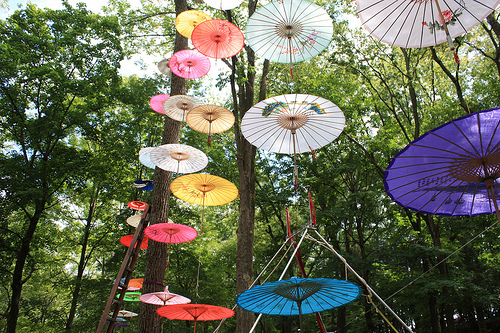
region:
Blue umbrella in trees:
[237, 272, 369, 316]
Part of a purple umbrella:
[375, 113, 497, 230]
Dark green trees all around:
[7, 20, 104, 295]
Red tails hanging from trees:
[272, 180, 338, 267]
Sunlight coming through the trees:
[114, 44, 156, 76]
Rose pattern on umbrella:
[422, 5, 477, 36]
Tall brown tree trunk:
[238, 163, 266, 273]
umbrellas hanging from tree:
[100, 6, 233, 328]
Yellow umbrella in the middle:
[172, 174, 244, 204]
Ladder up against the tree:
[113, 226, 136, 331]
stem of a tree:
[224, 233, 260, 286]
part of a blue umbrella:
[280, 282, 343, 308]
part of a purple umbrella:
[415, 142, 475, 209]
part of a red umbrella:
[166, 299, 230, 325]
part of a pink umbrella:
[153, 215, 188, 240]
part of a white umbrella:
[271, 115, 316, 162]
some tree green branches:
[11, 67, 88, 225]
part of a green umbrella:
[127, 292, 132, 307]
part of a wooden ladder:
[106, 278, 124, 298]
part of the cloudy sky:
[125, 47, 147, 72]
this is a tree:
[2, 10, 82, 331]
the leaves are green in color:
[11, 17, 88, 74]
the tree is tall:
[9, 8, 66, 327]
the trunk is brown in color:
[240, 158, 253, 288]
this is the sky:
[121, 57, 132, 75]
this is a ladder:
[107, 290, 121, 330]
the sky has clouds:
[120, 58, 136, 69]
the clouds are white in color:
[122, 56, 135, 79]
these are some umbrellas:
[159, 8, 206, 323]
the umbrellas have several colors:
[193, 22, 218, 204]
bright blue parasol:
[233, 269, 365, 320]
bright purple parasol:
[377, 92, 499, 215]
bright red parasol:
[194, 15, 239, 72]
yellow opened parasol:
[169, 162, 239, 219]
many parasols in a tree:
[144, 6, 362, 331]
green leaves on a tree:
[7, 13, 105, 199]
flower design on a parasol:
[419, 8, 469, 42]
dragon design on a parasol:
[260, 97, 330, 122]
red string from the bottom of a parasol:
[283, 196, 328, 252]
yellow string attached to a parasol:
[351, 283, 380, 331]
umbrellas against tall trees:
[98, 10, 471, 315]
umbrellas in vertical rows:
[110, 25, 360, 315]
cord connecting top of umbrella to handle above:
[185, 186, 210, 302]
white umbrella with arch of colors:
[231, 85, 351, 165]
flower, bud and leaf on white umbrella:
[357, 1, 492, 58]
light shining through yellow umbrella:
[160, 162, 245, 212]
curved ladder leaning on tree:
[80, 182, 160, 323]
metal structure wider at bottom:
[185, 206, 425, 321]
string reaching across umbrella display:
[336, 200, 493, 321]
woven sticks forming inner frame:
[257, 265, 339, 303]